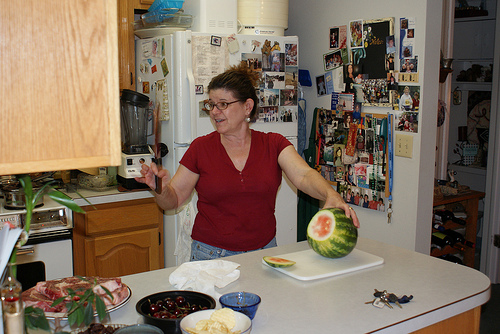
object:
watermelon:
[303, 209, 360, 257]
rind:
[263, 252, 293, 269]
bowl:
[214, 290, 260, 313]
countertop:
[279, 296, 313, 325]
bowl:
[136, 288, 221, 333]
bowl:
[179, 304, 256, 332]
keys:
[366, 283, 415, 313]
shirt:
[178, 129, 290, 253]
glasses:
[200, 96, 251, 109]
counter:
[430, 262, 474, 296]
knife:
[151, 106, 165, 153]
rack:
[434, 206, 482, 243]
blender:
[118, 87, 156, 192]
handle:
[155, 158, 163, 192]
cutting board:
[305, 257, 341, 274]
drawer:
[85, 210, 167, 227]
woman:
[134, 64, 358, 264]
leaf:
[46, 185, 89, 216]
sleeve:
[174, 137, 206, 175]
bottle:
[436, 205, 467, 226]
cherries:
[172, 294, 193, 309]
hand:
[321, 190, 362, 222]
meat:
[41, 283, 71, 299]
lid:
[120, 86, 151, 109]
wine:
[435, 208, 454, 221]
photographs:
[308, 17, 404, 209]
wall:
[286, 6, 327, 31]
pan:
[6, 181, 60, 192]